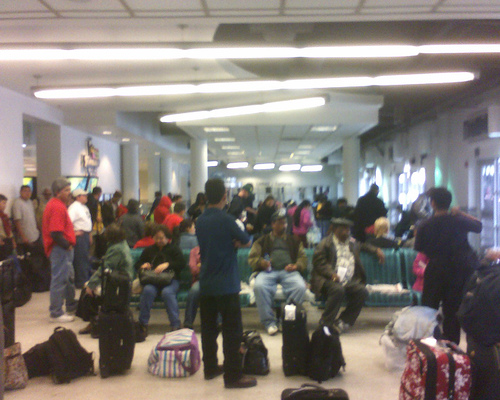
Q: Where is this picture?
A: At a terminal.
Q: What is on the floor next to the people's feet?
A: Luggage.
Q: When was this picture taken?
A: During the day.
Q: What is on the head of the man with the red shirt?
A: A hat.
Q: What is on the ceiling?
A: Lights.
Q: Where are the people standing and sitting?
A: In a airport.